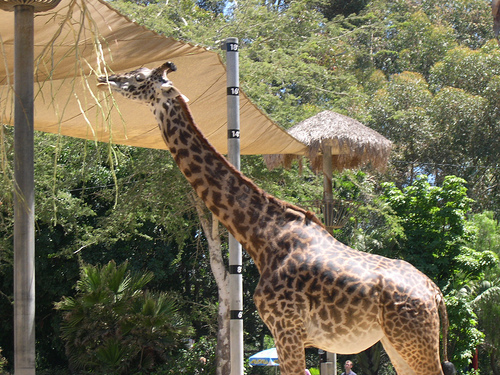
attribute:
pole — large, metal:
[218, 30, 248, 368]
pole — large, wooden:
[315, 142, 341, 374]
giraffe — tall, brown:
[95, 58, 452, 370]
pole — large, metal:
[222, 33, 246, 373]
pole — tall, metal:
[0, 76, 84, 260]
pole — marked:
[217, 35, 256, 371]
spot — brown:
[190, 152, 204, 164]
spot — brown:
[185, 124, 193, 134]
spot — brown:
[350, 295, 360, 307]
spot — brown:
[383, 290, 393, 300]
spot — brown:
[308, 312, 318, 332]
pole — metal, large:
[1, 0, 56, 373]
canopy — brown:
[3, 7, 320, 181]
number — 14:
[228, 127, 242, 139]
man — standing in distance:
[340, 357, 362, 374]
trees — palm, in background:
[48, 148, 168, 359]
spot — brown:
[331, 283, 350, 311]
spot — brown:
[322, 298, 352, 328]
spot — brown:
[397, 308, 408, 324]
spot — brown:
[345, 313, 368, 333]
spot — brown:
[265, 296, 288, 324]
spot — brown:
[285, 259, 297, 276]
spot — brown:
[223, 189, 238, 210]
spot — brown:
[163, 116, 178, 136]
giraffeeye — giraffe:
[133, 75, 145, 85]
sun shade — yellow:
[2, 1, 302, 159]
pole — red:
[470, 341, 480, 373]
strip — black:
[222, 130, 243, 140]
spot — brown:
[244, 221, 268, 251]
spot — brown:
[204, 181, 229, 213]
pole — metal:
[201, 20, 261, 371]